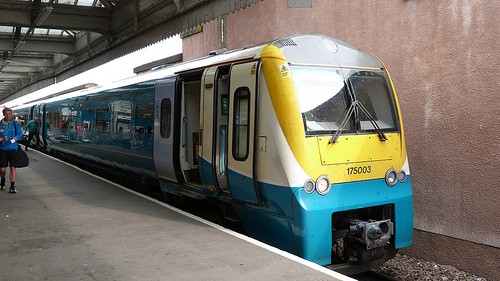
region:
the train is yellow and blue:
[76, 46, 390, 279]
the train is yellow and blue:
[67, 48, 251, 253]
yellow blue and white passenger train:
[249, 48, 406, 233]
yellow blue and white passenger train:
[170, 63, 277, 191]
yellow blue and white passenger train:
[117, 79, 184, 162]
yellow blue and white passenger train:
[77, 93, 151, 161]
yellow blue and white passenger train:
[35, 101, 111, 148]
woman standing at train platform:
[3, 111, 30, 190]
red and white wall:
[408, 21, 483, 164]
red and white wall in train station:
[420, 24, 486, 167]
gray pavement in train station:
[37, 211, 135, 256]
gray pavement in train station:
[40, 173, 81, 224]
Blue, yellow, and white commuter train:
[24, 53, 391, 255]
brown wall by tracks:
[202, 3, 497, 213]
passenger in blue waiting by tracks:
[0, 107, 31, 168]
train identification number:
[340, 152, 386, 179]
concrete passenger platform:
[0, 140, 221, 276]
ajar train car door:
[155, 70, 237, 186]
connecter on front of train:
[340, 212, 391, 254]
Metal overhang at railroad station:
[0, 12, 195, 59]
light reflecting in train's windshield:
[272, 25, 370, 125]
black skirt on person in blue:
[1, 151, 33, 171]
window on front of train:
[296, 67, 396, 131]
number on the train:
[340, 163, 385, 187]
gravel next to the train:
[399, 248, 441, 279]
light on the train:
[293, 171, 337, 213]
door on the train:
[143, 91, 249, 175]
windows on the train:
[41, 95, 154, 140]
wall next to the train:
[428, 42, 485, 99]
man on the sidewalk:
[0, 92, 53, 159]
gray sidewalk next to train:
[39, 196, 127, 247]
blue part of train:
[273, 206, 323, 254]